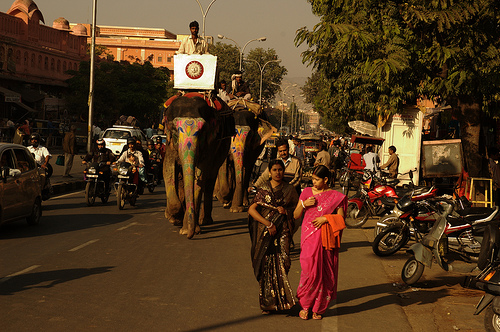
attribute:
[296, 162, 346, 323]
woman — young, walking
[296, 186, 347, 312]
clothing — pink, dark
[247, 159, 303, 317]
woman — walking, young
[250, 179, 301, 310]
clothing — brown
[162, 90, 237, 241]
elephant — large, walking, grey, painted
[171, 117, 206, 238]
trunk — multi-colored, decorated, colorful, painted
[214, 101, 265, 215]
elephant — walking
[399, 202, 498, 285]
motorcycle — parked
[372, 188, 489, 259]
motorcycle — parked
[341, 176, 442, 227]
motorcycle — parked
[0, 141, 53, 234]
vehicle — driving, white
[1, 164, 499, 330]
street — paved, grey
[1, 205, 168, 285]
line — dashed, white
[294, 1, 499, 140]
tree — green, large, leafy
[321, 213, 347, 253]
fabric — orange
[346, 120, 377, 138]
umbrella — white, grey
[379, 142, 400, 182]
person — standing